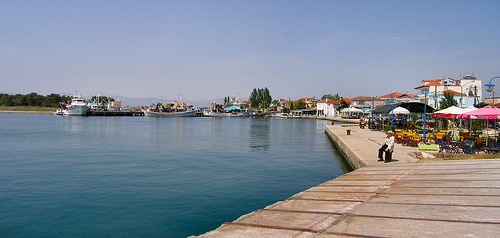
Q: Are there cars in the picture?
A: No, there are no cars.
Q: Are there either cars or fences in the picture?
A: No, there are no cars or fences.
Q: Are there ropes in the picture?
A: No, there are no ropes.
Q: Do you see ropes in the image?
A: No, there are no ropes.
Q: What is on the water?
A: The boats are on the water.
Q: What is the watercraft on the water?
A: The watercraft is boats.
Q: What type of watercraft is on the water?
A: The watercraft is boats.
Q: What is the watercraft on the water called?
A: The watercraft is boats.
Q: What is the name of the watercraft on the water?
A: The watercraft is boats.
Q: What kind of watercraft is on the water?
A: The watercraft is boats.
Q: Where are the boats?
A: The boats are on the water.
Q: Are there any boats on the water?
A: Yes, there are boats on the water.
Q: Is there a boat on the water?
A: Yes, there are boats on the water.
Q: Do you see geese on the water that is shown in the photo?
A: No, there are boats on the water.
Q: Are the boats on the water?
A: Yes, the boats are on the water.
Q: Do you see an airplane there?
A: No, there are no airplanes.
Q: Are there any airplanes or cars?
A: No, there are no airplanes or cars.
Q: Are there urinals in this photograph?
A: No, there are no urinals.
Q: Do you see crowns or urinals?
A: No, there are no urinals or crowns.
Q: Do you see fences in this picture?
A: No, there are no fences.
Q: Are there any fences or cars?
A: No, there are no fences or cars.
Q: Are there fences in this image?
A: No, there are no fences.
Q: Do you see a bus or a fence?
A: No, there are no fences or buses.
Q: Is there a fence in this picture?
A: No, there are no fences.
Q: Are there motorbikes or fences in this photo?
A: No, there are no fences or motorbikes.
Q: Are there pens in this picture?
A: No, there are no pens.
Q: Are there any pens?
A: No, there are no pens.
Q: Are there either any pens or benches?
A: No, there are no pens or benches.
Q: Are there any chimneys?
A: No, there are no chimneys.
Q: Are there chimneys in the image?
A: No, there are no chimneys.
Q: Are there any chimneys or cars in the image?
A: No, there are no chimneys or cars.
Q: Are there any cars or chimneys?
A: No, there are no chimneys or cars.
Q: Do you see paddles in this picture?
A: No, there are no paddles.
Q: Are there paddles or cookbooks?
A: No, there are no paddles or cookbooks.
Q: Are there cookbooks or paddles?
A: No, there are no paddles or cookbooks.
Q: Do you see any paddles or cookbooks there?
A: No, there are no paddles or cookbooks.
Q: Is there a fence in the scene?
A: No, there are no fences.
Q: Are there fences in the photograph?
A: No, there are no fences.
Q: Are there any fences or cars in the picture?
A: No, there are no fences or cars.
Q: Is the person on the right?
A: Yes, the person is on the right of the image.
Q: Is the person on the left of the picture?
A: No, the person is on the right of the image.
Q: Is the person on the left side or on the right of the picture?
A: The person is on the right of the image.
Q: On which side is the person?
A: The person is on the right of the image.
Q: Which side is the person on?
A: The person is on the right of the image.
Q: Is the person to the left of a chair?
A: Yes, the person is to the left of a chair.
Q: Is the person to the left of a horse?
A: No, the person is to the left of a chair.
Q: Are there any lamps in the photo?
A: No, there are no lamps.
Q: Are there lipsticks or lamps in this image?
A: No, there are no lamps or lipsticks.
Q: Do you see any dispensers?
A: No, there are no dispensers.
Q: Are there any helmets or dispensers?
A: No, there are no dispensers or helmets.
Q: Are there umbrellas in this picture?
A: Yes, there is an umbrella.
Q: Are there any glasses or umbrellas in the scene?
A: Yes, there is an umbrella.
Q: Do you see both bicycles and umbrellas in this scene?
A: No, there is an umbrella but no bikes.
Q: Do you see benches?
A: No, there are no benches.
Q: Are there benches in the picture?
A: No, there are no benches.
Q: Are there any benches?
A: No, there are no benches.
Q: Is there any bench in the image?
A: No, there are no benches.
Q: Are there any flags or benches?
A: No, there are no benches or flags.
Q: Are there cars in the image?
A: No, there are no cars.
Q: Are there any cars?
A: No, there are no cars.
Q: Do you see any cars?
A: No, there are no cars.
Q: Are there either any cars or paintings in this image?
A: No, there are no cars or paintings.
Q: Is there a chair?
A: Yes, there is a chair.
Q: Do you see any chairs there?
A: Yes, there is a chair.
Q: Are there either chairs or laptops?
A: Yes, there is a chair.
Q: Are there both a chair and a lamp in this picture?
A: No, there is a chair but no lamps.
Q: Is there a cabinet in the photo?
A: No, there are no cabinets.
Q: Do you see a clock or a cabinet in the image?
A: No, there are no cabinets or clocks.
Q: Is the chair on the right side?
A: Yes, the chair is on the right of the image.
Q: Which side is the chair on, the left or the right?
A: The chair is on the right of the image.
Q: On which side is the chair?
A: The chair is on the right of the image.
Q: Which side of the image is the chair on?
A: The chair is on the right of the image.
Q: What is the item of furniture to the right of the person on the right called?
A: The piece of furniture is a chair.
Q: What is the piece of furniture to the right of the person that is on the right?
A: The piece of furniture is a chair.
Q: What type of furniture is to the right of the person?
A: The piece of furniture is a chair.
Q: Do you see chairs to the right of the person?
A: Yes, there is a chair to the right of the person.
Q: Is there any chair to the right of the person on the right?
A: Yes, there is a chair to the right of the person.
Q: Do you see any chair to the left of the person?
A: No, the chair is to the right of the person.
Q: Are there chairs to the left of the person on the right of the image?
A: No, the chair is to the right of the person.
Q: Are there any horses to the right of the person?
A: No, there is a chair to the right of the person.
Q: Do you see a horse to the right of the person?
A: No, there is a chair to the right of the person.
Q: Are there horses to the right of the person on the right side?
A: No, there is a chair to the right of the person.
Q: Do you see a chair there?
A: Yes, there is a chair.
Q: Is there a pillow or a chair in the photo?
A: Yes, there is a chair.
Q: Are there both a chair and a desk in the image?
A: No, there is a chair but no desks.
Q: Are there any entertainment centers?
A: No, there are no entertainment centers.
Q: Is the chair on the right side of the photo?
A: Yes, the chair is on the right of the image.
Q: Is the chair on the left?
A: No, the chair is on the right of the image.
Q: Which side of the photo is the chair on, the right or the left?
A: The chair is on the right of the image.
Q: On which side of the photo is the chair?
A: The chair is on the right of the image.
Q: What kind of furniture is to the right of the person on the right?
A: The piece of furniture is a chair.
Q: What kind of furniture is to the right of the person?
A: The piece of furniture is a chair.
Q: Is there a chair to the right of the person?
A: Yes, there is a chair to the right of the person.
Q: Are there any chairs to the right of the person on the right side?
A: Yes, there is a chair to the right of the person.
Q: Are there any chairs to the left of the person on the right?
A: No, the chair is to the right of the person.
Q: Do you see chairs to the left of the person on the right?
A: No, the chair is to the right of the person.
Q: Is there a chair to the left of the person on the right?
A: No, the chair is to the right of the person.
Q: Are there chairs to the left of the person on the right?
A: No, the chair is to the right of the person.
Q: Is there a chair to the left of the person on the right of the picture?
A: No, the chair is to the right of the person.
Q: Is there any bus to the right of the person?
A: No, there is a chair to the right of the person.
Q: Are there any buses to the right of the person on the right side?
A: No, there is a chair to the right of the person.